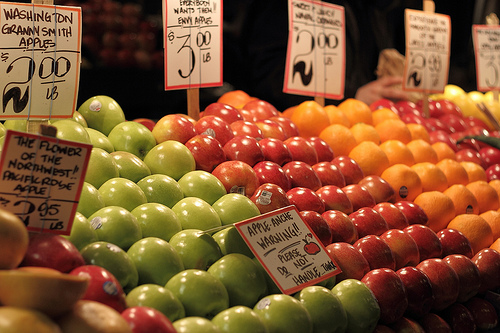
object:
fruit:
[0, 84, 500, 333]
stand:
[0, 0, 499, 332]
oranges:
[283, 97, 500, 257]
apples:
[143, 140, 196, 180]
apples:
[177, 170, 227, 206]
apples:
[211, 192, 261, 226]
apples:
[107, 121, 156, 161]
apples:
[78, 95, 125, 137]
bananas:
[428, 84, 500, 130]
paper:
[0, 2, 83, 121]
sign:
[283, 0, 345, 100]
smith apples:
[86, 174, 181, 252]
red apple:
[282, 161, 320, 192]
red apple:
[311, 161, 346, 188]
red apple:
[315, 184, 353, 215]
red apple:
[340, 184, 376, 210]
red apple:
[373, 201, 409, 230]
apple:
[0, 94, 500, 333]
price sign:
[162, 0, 224, 91]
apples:
[0, 95, 381, 333]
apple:
[184, 134, 226, 173]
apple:
[284, 135, 321, 162]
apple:
[358, 174, 395, 202]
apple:
[286, 186, 326, 214]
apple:
[379, 229, 419, 266]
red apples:
[282, 155, 396, 214]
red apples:
[299, 208, 371, 280]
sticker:
[398, 185, 408, 198]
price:
[402, 8, 451, 94]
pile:
[150, 91, 499, 322]